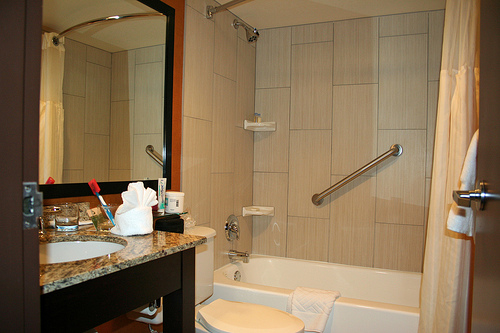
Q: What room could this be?
A: It is a bathroom.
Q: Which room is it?
A: It is a bathroom.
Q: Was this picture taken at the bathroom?
A: Yes, it was taken in the bathroom.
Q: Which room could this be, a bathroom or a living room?
A: It is a bathroom.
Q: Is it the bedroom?
A: No, it is the bathroom.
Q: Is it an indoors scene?
A: Yes, it is indoors.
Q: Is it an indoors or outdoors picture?
A: It is indoors.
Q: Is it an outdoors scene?
A: No, it is indoors.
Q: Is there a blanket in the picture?
A: No, there are no blankets.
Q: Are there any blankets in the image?
A: No, there are no blankets.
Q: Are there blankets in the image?
A: No, there are no blankets.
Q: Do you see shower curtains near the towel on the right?
A: Yes, there is a shower curtain near the towel.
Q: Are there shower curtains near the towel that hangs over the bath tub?
A: Yes, there is a shower curtain near the towel.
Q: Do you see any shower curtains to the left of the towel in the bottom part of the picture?
A: No, the shower curtain is to the right of the towel.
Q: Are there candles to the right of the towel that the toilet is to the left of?
A: No, there is a shower curtain to the right of the towel.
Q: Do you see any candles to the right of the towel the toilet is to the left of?
A: No, there is a shower curtain to the right of the towel.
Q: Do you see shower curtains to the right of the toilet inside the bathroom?
A: Yes, there is a shower curtain to the right of the toilet.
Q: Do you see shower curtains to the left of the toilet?
A: No, the shower curtain is to the right of the toilet.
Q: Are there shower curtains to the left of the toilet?
A: No, the shower curtain is to the right of the toilet.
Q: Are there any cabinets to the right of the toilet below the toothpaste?
A: No, there is a shower curtain to the right of the toilet.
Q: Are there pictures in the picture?
A: No, there are no pictures.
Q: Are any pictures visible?
A: No, there are no pictures.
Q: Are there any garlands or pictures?
A: No, there are no pictures or garlands.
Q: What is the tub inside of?
A: The tub is inside the bathroom.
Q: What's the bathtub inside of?
A: The tub is inside the bathroom.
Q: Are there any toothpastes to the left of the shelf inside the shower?
A: Yes, there is a toothpaste to the left of the shelf.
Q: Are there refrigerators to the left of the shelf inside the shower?
A: No, there is a toothpaste to the left of the shelf.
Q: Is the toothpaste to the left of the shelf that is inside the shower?
A: Yes, the toothpaste is to the left of the shelf.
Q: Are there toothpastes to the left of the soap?
A: Yes, there is a toothpaste to the left of the soap.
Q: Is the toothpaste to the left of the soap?
A: Yes, the toothpaste is to the left of the soap.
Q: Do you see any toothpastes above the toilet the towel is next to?
A: Yes, there is a toothpaste above the toilet.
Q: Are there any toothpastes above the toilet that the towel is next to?
A: Yes, there is a toothpaste above the toilet.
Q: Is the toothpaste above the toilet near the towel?
A: Yes, the toothpaste is above the toilet.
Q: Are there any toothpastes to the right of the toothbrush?
A: Yes, there is a toothpaste to the right of the toothbrush.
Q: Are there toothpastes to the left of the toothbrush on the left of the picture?
A: No, the toothpaste is to the right of the toothbrush.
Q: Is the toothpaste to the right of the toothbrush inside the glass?
A: Yes, the toothpaste is to the right of the toothbrush.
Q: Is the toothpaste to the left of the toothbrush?
A: No, the toothpaste is to the right of the toothbrush.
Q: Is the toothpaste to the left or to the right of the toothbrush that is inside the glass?
A: The toothpaste is to the right of the toothbrush.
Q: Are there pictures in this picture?
A: No, there are no pictures.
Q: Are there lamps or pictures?
A: No, there are no pictures or lamps.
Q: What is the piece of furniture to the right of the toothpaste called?
A: The piece of furniture is a shelf.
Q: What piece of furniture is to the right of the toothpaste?
A: The piece of furniture is a shelf.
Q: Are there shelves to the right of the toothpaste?
A: Yes, there is a shelf to the right of the toothpaste.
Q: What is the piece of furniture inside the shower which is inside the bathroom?
A: The piece of furniture is a shelf.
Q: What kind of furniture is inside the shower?
A: The piece of furniture is a shelf.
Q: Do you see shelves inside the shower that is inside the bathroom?
A: Yes, there is a shelf inside the shower.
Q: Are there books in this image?
A: No, there are no books.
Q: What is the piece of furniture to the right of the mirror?
A: The piece of furniture is a shelf.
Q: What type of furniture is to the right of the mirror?
A: The piece of furniture is a shelf.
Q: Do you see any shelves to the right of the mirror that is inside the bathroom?
A: Yes, there is a shelf to the right of the mirror.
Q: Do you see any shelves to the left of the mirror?
A: No, the shelf is to the right of the mirror.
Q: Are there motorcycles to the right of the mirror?
A: No, there is a shelf to the right of the mirror.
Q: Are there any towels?
A: Yes, there is a towel.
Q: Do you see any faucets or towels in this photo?
A: Yes, there is a towel.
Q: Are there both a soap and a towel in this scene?
A: Yes, there are both a towel and a soap.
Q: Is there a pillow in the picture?
A: No, there are no pillows.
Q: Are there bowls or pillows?
A: No, there are no pillows or bowls.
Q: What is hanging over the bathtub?
A: The towel is hanging over the bathtub.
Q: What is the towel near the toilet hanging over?
A: The towel is hanging over the bathtub.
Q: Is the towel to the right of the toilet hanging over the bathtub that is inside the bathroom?
A: Yes, the towel is hanging over the bathtub.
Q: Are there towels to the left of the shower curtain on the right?
A: Yes, there is a towel to the left of the shower curtain.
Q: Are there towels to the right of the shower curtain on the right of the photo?
A: No, the towel is to the left of the shower curtain.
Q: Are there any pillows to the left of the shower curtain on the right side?
A: No, there is a towel to the left of the shower curtain.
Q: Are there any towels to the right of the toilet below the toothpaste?
A: Yes, there is a towel to the right of the toilet.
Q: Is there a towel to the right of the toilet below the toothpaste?
A: Yes, there is a towel to the right of the toilet.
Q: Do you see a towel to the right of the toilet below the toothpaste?
A: Yes, there is a towel to the right of the toilet.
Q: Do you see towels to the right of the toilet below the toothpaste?
A: Yes, there is a towel to the right of the toilet.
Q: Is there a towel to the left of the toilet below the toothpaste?
A: No, the towel is to the right of the toilet.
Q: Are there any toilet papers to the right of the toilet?
A: No, there is a towel to the right of the toilet.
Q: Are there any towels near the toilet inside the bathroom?
A: Yes, there is a towel near the toilet.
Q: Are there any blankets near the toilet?
A: No, there is a towel near the toilet.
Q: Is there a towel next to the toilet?
A: Yes, there is a towel next to the toilet.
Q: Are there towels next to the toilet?
A: Yes, there is a towel next to the toilet.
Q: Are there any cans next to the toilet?
A: No, there is a towel next to the toilet.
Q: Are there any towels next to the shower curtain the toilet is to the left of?
A: Yes, there is a towel next to the shower curtain.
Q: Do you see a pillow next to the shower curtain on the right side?
A: No, there is a towel next to the shower curtain.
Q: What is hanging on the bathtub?
A: The towel is hanging on the tub.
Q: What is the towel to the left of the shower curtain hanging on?
A: The towel is hanging on the bath tub.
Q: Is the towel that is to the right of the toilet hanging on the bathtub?
A: Yes, the towel is hanging on the bathtub.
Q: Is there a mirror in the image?
A: Yes, there is a mirror.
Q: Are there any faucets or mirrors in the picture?
A: Yes, there is a mirror.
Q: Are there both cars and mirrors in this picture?
A: No, there is a mirror but no cars.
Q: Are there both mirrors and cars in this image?
A: No, there is a mirror but no cars.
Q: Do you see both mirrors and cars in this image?
A: No, there is a mirror but no cars.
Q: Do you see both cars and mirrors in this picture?
A: No, there is a mirror but no cars.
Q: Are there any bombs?
A: No, there are no bombs.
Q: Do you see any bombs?
A: No, there are no bombs.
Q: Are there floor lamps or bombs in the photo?
A: No, there are no bombs or floor lamps.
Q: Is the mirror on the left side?
A: Yes, the mirror is on the left of the image.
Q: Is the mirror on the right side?
A: No, the mirror is on the left of the image.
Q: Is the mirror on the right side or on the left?
A: The mirror is on the left of the image.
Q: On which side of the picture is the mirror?
A: The mirror is on the left of the image.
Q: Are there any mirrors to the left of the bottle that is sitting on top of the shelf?
A: Yes, there is a mirror to the left of the bottle.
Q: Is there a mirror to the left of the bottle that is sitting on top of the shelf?
A: Yes, there is a mirror to the left of the bottle.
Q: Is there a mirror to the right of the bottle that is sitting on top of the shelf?
A: No, the mirror is to the left of the bottle.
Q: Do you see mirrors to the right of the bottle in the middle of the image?
A: No, the mirror is to the left of the bottle.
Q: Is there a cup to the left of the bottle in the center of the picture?
A: No, there is a mirror to the left of the bottle.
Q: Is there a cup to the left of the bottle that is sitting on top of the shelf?
A: No, there is a mirror to the left of the bottle.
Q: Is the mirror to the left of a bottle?
A: Yes, the mirror is to the left of a bottle.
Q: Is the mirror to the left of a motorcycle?
A: No, the mirror is to the left of a bottle.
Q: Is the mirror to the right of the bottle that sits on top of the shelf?
A: No, the mirror is to the left of the bottle.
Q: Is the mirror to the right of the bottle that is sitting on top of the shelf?
A: No, the mirror is to the left of the bottle.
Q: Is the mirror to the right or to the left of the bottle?
A: The mirror is to the left of the bottle.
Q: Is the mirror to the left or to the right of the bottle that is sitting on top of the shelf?
A: The mirror is to the left of the bottle.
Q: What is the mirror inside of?
A: The mirror is inside the bathroom.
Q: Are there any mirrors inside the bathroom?
A: Yes, there is a mirror inside the bathroom.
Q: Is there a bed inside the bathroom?
A: No, there is a mirror inside the bathroom.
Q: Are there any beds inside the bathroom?
A: No, there is a mirror inside the bathroom.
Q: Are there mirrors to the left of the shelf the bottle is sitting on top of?
A: Yes, there is a mirror to the left of the shelf.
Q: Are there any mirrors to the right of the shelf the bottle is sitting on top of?
A: No, the mirror is to the left of the shelf.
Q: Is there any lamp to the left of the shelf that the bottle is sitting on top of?
A: No, there is a mirror to the left of the shelf.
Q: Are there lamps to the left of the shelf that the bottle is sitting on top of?
A: No, there is a mirror to the left of the shelf.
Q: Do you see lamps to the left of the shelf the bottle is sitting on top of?
A: No, there is a mirror to the left of the shelf.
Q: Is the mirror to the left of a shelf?
A: Yes, the mirror is to the left of a shelf.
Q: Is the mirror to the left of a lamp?
A: No, the mirror is to the left of a shelf.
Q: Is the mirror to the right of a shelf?
A: No, the mirror is to the left of a shelf.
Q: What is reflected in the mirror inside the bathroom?
A: The shower curtain is reflected in the mirror.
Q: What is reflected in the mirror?
A: The shower curtain is reflected in the mirror.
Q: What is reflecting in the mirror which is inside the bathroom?
A: The shower curtain is reflecting in the mirror.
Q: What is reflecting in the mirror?
A: The shower curtain is reflecting in the mirror.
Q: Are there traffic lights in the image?
A: No, there are no traffic lights.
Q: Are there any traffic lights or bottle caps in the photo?
A: No, there are no traffic lights or bottle caps.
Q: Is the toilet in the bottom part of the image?
A: Yes, the toilet is in the bottom of the image.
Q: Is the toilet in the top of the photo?
A: No, the toilet is in the bottom of the image.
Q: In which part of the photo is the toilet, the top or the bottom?
A: The toilet is in the bottom of the image.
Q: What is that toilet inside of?
A: The toilet is inside the bathroom.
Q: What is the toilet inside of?
A: The toilet is inside the bathroom.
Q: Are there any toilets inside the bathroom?
A: Yes, there is a toilet inside the bathroom.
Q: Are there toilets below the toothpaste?
A: Yes, there is a toilet below the toothpaste.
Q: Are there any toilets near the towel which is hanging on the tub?
A: Yes, there is a toilet near the towel.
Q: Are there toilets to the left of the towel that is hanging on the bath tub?
A: Yes, there is a toilet to the left of the towel.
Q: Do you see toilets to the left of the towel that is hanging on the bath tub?
A: Yes, there is a toilet to the left of the towel.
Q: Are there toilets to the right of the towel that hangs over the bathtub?
A: No, the toilet is to the left of the towel.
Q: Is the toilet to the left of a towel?
A: Yes, the toilet is to the left of a towel.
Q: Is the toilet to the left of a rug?
A: No, the toilet is to the left of a towel.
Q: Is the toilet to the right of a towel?
A: No, the toilet is to the left of a towel.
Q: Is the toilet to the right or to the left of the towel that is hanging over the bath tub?
A: The toilet is to the left of the towel.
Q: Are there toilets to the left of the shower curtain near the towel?
A: Yes, there is a toilet to the left of the shower curtain.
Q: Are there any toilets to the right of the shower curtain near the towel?
A: No, the toilet is to the left of the shower curtain.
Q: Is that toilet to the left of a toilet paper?
A: No, the toilet is to the left of the shower curtain.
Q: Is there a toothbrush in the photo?
A: Yes, there is a toothbrush.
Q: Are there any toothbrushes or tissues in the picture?
A: Yes, there is a toothbrush.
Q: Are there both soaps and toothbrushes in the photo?
A: Yes, there are both a toothbrush and a soap.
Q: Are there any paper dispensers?
A: No, there are no paper dispensers.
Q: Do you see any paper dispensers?
A: No, there are no paper dispensers.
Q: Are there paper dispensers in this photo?
A: No, there are no paper dispensers.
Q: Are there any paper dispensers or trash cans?
A: No, there are no paper dispensers or trash cans.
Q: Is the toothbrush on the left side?
A: Yes, the toothbrush is on the left of the image.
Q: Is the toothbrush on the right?
A: No, the toothbrush is on the left of the image.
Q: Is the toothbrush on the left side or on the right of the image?
A: The toothbrush is on the left of the image.